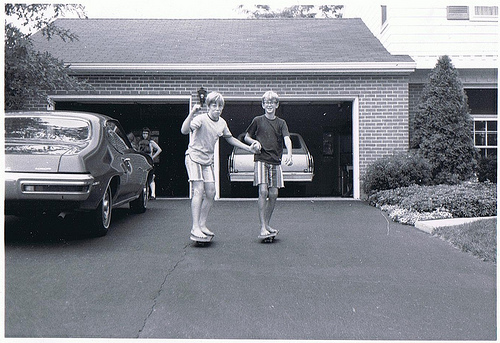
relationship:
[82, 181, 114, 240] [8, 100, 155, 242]
tire on car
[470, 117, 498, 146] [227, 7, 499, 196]
window in front of house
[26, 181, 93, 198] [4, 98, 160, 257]
brake light on car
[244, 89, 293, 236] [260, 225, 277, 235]
boy has feet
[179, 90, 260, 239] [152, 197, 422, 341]
boy skateboarding in driveway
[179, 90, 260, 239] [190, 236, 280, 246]
boy on skateboards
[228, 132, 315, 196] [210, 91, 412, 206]
car in garage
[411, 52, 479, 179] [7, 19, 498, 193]
bush in front of house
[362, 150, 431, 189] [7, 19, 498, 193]
bush in front of house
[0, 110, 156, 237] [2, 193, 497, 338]
car on driveway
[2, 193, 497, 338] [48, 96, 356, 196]
driveway in front of garage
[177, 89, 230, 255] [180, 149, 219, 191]
boy wears shorts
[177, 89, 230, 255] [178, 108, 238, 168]
boy wears tee shirt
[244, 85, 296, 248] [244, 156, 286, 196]
boy wears shorts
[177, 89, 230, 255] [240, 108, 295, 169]
boy wears tee shirt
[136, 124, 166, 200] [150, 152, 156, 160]
woman has hand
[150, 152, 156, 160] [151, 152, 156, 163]
hand on hip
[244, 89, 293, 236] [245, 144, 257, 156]
boy raises hand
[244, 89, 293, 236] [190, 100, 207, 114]
boy raises hand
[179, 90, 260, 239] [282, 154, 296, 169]
boy raises hand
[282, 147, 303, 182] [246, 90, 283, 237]
car behind boy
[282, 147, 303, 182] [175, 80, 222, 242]
car behind boy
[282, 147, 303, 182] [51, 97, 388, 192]
car in garage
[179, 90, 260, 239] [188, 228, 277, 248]
boy on skateboards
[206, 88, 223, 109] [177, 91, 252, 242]
hair on boy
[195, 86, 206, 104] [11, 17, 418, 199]
light on garage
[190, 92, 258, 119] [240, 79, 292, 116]
glasses on face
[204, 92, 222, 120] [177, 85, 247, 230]
head on person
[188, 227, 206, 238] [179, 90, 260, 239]
foot on boy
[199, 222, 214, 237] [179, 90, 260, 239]
foot on boy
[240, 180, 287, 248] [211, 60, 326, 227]
leg on person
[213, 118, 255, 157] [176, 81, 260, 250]
arm on person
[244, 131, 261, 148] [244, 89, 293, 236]
arm of boy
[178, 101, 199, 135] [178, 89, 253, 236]
arm of person